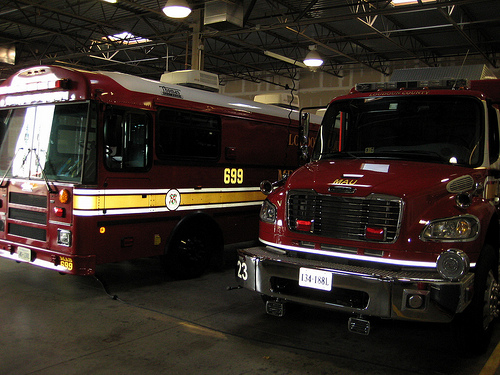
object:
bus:
[0, 65, 340, 283]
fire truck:
[236, 75, 498, 336]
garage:
[7, 3, 497, 368]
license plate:
[299, 266, 333, 291]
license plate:
[17, 247, 31, 262]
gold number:
[224, 168, 245, 185]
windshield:
[331, 95, 491, 164]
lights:
[356, 78, 472, 94]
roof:
[337, 91, 498, 95]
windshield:
[5, 108, 87, 178]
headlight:
[423, 218, 479, 241]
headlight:
[260, 201, 278, 223]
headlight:
[58, 230, 71, 247]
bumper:
[237, 246, 470, 323]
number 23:
[237, 260, 249, 281]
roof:
[79, 77, 292, 108]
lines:
[72, 186, 278, 217]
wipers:
[315, 146, 452, 159]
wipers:
[1, 147, 56, 193]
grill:
[289, 192, 398, 242]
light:
[161, 0, 192, 18]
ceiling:
[3, 4, 499, 73]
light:
[303, 50, 323, 66]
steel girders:
[261, 17, 381, 74]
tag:
[333, 179, 358, 186]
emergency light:
[295, 218, 314, 233]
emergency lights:
[364, 227, 387, 241]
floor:
[8, 327, 499, 369]